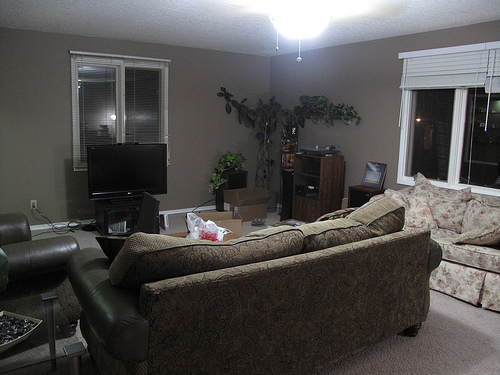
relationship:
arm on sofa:
[69, 247, 150, 363] [67, 194, 443, 374]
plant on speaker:
[207, 150, 246, 192] [216, 170, 249, 209]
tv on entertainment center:
[86, 143, 168, 198] [97, 197, 160, 232]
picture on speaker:
[361, 160, 387, 187] [347, 183, 385, 206]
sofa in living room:
[67, 194, 443, 374] [0, 0, 498, 375]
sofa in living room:
[371, 171, 499, 314] [0, 0, 498, 375]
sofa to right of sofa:
[371, 171, 499, 314] [67, 194, 443, 374]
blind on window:
[397, 43, 489, 129] [398, 88, 500, 197]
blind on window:
[484, 41, 498, 131] [398, 88, 500, 197]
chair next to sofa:
[0, 212, 81, 336] [67, 194, 443, 374]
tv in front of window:
[86, 143, 168, 198] [71, 53, 170, 170]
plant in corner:
[217, 85, 290, 211] [218, 48, 309, 207]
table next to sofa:
[0, 289, 87, 374] [67, 194, 443, 374]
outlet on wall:
[29, 199, 39, 212] [0, 29, 272, 225]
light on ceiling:
[271, 11, 331, 42] [0, 1, 499, 57]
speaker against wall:
[216, 170, 249, 209] [0, 29, 272, 225]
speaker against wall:
[347, 183, 385, 206] [268, 23, 499, 209]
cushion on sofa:
[107, 225, 307, 288] [67, 194, 443, 374]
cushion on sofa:
[296, 193, 405, 252] [67, 194, 443, 374]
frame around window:
[70, 53, 175, 172] [71, 53, 170, 170]